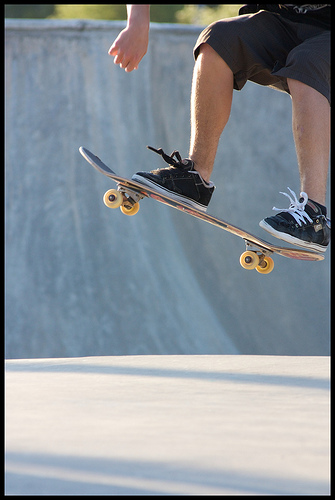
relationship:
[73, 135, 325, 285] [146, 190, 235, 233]
skateboard with accents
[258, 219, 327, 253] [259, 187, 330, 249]
bottom of shoe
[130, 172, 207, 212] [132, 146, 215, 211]
bottom of shoe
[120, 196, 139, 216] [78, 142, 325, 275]
wheel on skateboard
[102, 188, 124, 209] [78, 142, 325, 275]
wheel on skateboard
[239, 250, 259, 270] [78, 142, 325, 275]
wheel on skateboard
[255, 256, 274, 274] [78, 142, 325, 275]
wheel on skateboard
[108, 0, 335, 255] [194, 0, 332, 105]
man wearing shorts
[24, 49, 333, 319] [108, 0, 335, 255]
concrete barrier behind man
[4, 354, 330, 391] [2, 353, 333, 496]
shadow on ground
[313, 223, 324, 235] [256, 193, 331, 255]
tag on shoe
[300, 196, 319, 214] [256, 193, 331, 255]
tag on shoe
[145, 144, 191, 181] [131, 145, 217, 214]
lace on shoe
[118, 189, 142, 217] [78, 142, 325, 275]
wheel on skateboard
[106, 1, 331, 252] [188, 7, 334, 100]
man wearing shorts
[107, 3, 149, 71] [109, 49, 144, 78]
hand pointing downward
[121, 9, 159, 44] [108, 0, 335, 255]
wrist of man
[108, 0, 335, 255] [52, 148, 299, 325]
man riding skateboard